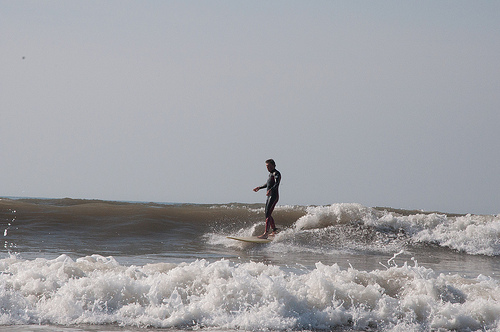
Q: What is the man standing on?
A: Surfboard.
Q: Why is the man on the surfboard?
A: He is surfing.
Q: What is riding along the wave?
A: Man on surfboard.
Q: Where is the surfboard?
A: Underneath the man in the wetsuit.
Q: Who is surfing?
A: The man in the wetsuit.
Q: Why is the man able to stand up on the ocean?
A: He is riding a surfboard.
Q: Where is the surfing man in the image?
A: Center.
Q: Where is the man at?
A: Ocean.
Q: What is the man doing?
A: Surfing.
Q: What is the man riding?
A: Wave.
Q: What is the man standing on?
A: Surfboard.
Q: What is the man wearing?
A: Wetsuit.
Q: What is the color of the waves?
A: White.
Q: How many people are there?
A: 1.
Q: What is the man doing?
A: Wakeboarding.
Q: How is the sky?
A: Clear.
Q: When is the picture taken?
A: Daytime.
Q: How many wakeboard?
A: One.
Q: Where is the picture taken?
A: At the beach.